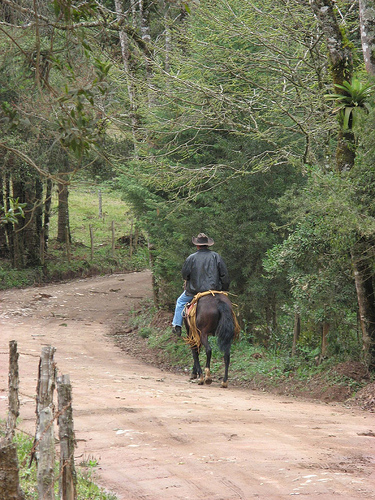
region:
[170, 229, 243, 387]
a man riding a horse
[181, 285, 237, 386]
a dark brown horse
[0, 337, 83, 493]
a barbed wire wood fence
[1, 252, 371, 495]
a dirt road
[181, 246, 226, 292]
a men's black jacket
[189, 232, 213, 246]
a brown cowboy hat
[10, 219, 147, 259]
a barbed wire fence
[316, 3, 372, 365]
a tall tree trunk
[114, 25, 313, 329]
a large green tree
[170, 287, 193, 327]
men's blue jeans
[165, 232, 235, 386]
a man on a horse going down a dirt road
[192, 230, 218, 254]
a man wearing a cowboy hat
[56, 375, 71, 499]
a wooden fence post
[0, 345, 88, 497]
wooden wire fence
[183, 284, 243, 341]
a brown saddle on a horse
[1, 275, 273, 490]
dirt road that horse is on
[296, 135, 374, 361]
green evergreen trees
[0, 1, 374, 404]
many green trees on side of road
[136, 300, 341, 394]
green grass and weeds on side of road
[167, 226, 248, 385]
a black horse and man are trotting down the street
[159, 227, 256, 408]
a man riding a horse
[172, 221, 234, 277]
man wearing a brown hat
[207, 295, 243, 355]
tail of horse is black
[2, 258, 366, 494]
unpaved road of soil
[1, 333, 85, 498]
wood sticks holding strings of a fence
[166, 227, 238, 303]
man wears a black jacket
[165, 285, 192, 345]
a leg with blue jean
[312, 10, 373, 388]
a trunk of tree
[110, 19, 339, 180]
branches of tree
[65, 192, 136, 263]
field covered with grass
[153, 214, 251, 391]
Man riding on a horse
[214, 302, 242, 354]
The horse has a long tail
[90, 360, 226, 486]
The road is dusty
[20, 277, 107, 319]
There are rocks in the path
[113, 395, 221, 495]
Tracks on the dirt road path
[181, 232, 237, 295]
The man is wearing a cowboy hat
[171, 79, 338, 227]
Trees filled with leaves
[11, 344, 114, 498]
Barbed wire fence surrounding path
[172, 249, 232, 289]
Man wearing a leather jacket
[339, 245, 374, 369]
Trunk on the tree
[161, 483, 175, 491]
black mark is spotted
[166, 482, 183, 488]
black mark is spotted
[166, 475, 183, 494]
black mark is spotted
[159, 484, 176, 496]
black mark is spotted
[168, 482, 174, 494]
black mark is spotted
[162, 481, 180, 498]
black mark is spotted